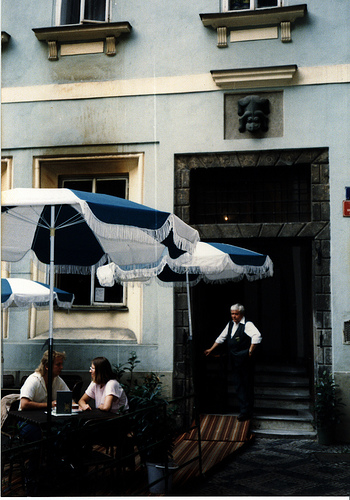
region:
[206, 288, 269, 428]
man wearing formal uniform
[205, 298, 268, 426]
man with silver hair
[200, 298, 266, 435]
older man wearing white collared shirt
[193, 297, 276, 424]
older man wearing black vest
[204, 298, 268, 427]
man wearing black pants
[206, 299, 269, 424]
man wearing black shoes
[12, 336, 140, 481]
two people seated at a table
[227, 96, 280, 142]
small decorative statue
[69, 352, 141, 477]
woman wearing eyeglasses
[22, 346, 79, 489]
man with long blonde hair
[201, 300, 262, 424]
person standing in doorway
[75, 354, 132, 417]
person seated at table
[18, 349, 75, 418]
person seated at table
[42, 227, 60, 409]
metal pole of an umbrella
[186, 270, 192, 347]
metal pole of an umbrella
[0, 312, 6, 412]
metal pole of an umbrella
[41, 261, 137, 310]
window on a building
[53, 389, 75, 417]
menu on a table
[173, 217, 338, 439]
doorway on a building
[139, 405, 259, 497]
brown rug with stripes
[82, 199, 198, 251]
white fringe on umbrella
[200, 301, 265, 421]
man wearing a dark vest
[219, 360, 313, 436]
stone stairs behind man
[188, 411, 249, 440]
striped mat on step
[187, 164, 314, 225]
transom window over door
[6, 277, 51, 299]
white panel on umbrella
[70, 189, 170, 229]
blue panel on umbrella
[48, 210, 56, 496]
pole supporting an open umbrella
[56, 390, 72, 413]
menu on table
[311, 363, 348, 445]
green potted plant next to doorway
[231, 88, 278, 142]
statue on the wall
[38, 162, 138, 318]
window of a building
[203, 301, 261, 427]
person with grey hair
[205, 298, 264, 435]
person standing in the doorway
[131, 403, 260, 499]
rug with brown stripes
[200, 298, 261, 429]
person wearing a vest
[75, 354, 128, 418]
person with brown hair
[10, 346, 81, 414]
person with blonde hair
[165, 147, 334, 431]
doorway to a building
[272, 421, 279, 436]
part of the surface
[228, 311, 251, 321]
head of a man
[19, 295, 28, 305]
part of an umbrella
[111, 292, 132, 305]
edge of a window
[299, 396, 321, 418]
part of a stair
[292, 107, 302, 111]
part of a building